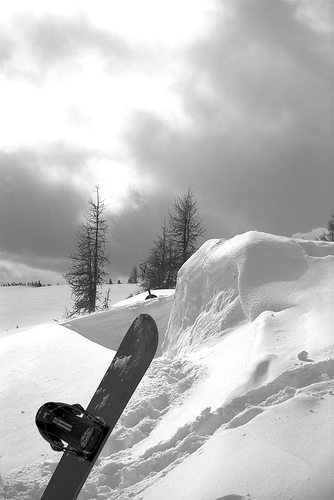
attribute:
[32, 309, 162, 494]
snowboard — black, grey, standing, dark, stuck, stuck vertically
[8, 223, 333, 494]
snow — white, piled, piled high, deep, here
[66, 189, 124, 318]
tree — bare, leafless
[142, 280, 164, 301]
handle — shovel's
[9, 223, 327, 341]
distance — snowy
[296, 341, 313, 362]
clump — snow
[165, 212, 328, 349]
rock — covered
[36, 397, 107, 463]
strap — boot's, black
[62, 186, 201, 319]
trees — barren, pine, several, leafless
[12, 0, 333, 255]
clouds — dark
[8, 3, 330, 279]
sky — filled, cloudy, bright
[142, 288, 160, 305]
shovel — stuck, sticking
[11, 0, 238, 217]
sun — peeking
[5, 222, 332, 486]
drift — snow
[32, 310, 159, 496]
ski — lone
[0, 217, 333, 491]
landscape — filled, snow filled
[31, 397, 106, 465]
boot — attached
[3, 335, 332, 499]
sets — tracks, several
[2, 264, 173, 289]
line — trees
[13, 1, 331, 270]
skies — cloudy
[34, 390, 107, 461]
holder — boot's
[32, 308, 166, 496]
something — standing, black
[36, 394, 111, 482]
binding — boot's, snowboard's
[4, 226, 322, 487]
bank — snow